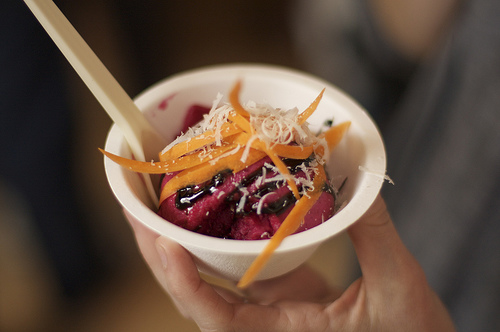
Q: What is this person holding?
A: Bowl.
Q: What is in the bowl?
A: Food.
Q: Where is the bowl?
A: In a person's hand.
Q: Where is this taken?
A: Maybe a restaurant.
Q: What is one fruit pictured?
A: Strawberries.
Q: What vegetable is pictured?
A: Slices of carrot.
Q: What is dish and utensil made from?
A: Plastic.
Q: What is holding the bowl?
A: A hand.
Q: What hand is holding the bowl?
A: The left hand.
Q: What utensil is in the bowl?
A: A spoon.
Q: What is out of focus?
A: The background.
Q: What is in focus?
A: The bowl, spoon, and hand.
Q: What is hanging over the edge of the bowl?
A: An orange piece of food.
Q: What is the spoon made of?
A: Plastic.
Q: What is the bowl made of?
A: Plastic.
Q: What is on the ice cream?
A: Shredded fruit.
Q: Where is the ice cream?
A: In the bowl.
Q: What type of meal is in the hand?
A: A dessert.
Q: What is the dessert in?
A: A cup.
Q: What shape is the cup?
A: The cup is circular.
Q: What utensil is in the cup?
A: The spoon.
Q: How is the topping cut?
A: The topping is sliced.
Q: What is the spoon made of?
A: The spoon is plastic.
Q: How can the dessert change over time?
A: It can melt.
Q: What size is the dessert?
A: One serving.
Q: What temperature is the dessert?
A: The dessert is cold.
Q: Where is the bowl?
A: In the person's hand.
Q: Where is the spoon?
A: In the bowl.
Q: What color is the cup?
A: White.